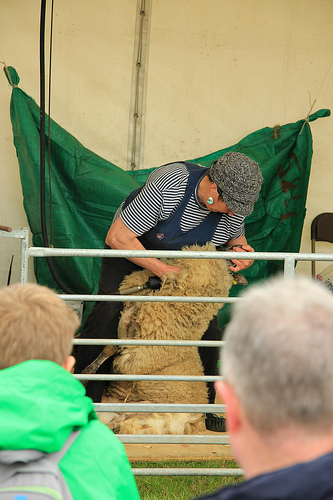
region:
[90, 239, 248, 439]
The sheep is white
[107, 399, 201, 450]
White wool on the ground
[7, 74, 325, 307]
The tarp is green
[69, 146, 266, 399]
The woman is shearing the sheep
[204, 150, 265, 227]
The woman is wearing a grey hat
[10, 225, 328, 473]
The sheep is behind a grey gate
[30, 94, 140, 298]
The cord is black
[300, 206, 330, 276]
The chair is silver and black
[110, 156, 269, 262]
Woman wearing a striped shirt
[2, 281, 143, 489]
Boy wearing a green jacket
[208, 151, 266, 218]
woman's grey hat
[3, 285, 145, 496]
boy wearing a green jacket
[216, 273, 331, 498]
man with grey hair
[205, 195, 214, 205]
the woman's shinny earing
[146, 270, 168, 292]
the woman's black shears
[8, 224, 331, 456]
large metal gate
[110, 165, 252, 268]
the woman's striped shirt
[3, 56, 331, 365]
large green tarp behind the woman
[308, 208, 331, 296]
part of a metal and plastic chair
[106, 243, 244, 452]
the sheep being sheared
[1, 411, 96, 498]
gray backpack with green stripe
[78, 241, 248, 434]
sheep being sheared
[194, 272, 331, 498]
old man watching sheep being sheared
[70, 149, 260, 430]
woman in overalls shearing a sheep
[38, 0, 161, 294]
shaver for shearing sheep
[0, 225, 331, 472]
metal fence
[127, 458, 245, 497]
short green grass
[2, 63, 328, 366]
green hanging tarp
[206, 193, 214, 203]
teardrop shaped teal black and silver earring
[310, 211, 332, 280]
black folding chair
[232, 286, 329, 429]
A white haired man's head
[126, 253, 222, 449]
A brown wooled sheep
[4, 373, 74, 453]
A green jacket hood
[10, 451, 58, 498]
A grey green zipped bag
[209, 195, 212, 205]
Beautiful green ear ring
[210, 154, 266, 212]
A grey thread hut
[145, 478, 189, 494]
Green short health grass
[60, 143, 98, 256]
A green hanging rug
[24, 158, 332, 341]
A metal fanced cage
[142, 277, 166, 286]
A black shaving machine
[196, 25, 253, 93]
this is the wall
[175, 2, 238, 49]
the wall is white in color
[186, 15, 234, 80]
the wall is clean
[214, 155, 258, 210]
this is a cap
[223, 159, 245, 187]
the cap is grey in color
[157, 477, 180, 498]
this is the grass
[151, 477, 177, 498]
the grass is green in color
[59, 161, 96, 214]
this is a cloth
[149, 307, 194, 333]
the fur is brown in color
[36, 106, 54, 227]
this is a pipe